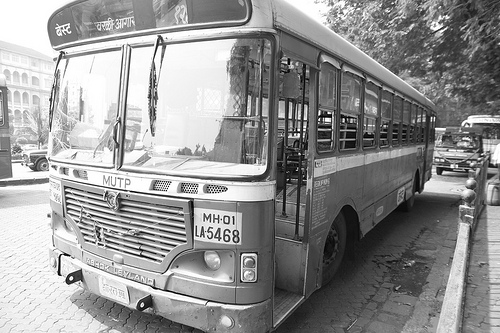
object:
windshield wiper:
[49, 51, 66, 133]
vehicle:
[21, 149, 48, 171]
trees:
[314, 0, 499, 124]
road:
[0, 166, 497, 333]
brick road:
[0, 180, 499, 332]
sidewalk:
[465, 205, 500, 322]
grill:
[61, 179, 193, 274]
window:
[316, 61, 339, 154]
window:
[340, 71, 364, 152]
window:
[361, 81, 380, 147]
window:
[380, 87, 393, 149]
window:
[392, 95, 402, 148]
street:
[0, 158, 500, 333]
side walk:
[408, 149, 499, 331]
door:
[269, 33, 321, 326]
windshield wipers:
[147, 35, 163, 136]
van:
[433, 126, 485, 175]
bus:
[44, 0, 435, 333]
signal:
[240, 253, 258, 283]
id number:
[193, 208, 242, 246]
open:
[271, 55, 309, 328]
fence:
[458, 150, 490, 236]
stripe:
[312, 145, 425, 177]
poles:
[282, 97, 289, 218]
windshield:
[48, 36, 273, 177]